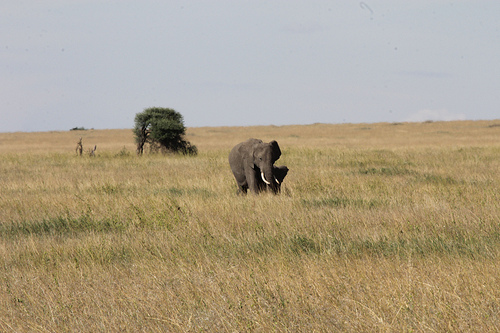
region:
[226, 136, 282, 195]
a bull elephant in the plains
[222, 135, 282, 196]
a lone elephant on the move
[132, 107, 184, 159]
a tree in the plains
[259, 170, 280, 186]
the tusks of the bull elephant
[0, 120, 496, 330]
a grassy plains area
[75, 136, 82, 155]
an old rotten tree trunk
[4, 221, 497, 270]
a strip of green grass in the plains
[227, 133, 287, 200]
an elephant moving across the plains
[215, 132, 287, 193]
elephant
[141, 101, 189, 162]
elephant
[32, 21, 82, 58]
white clouds in blue sky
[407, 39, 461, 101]
white clouds in blue sky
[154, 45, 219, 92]
white clouds in blue sky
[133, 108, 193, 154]
a leafy tree on the scene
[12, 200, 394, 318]
a lot of grass in the field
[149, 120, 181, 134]
many green tree leaves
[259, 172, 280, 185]
two elephant tusks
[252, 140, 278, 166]
the head of the elephant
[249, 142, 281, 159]
the two ears of the elephant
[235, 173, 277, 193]
the legs of the elephant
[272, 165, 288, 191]
looks like the shadow of the elephant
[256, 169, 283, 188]
elephant has two tusks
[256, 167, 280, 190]
tusks of elephant are white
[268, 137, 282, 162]
right ear of elephant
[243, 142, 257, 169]
left ear of elephant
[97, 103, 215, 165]
a green tree in a field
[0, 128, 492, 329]
field is covered with dry grass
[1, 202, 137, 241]
patch of green grass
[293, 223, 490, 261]
patch of green grass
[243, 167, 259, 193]
front feet of elephant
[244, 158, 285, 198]
tusks on the elephant's face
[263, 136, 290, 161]
ear of the elephant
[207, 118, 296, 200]
gray elephant in photo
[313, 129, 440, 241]
brown and green grass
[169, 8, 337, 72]
blue sky above land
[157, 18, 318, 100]
sky above the land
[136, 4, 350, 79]
sky with no clouds